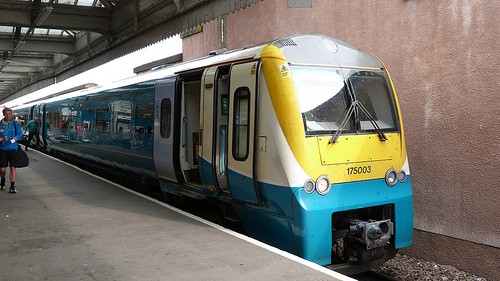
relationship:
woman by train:
[4, 131, 34, 201] [84, 28, 422, 255]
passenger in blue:
[0, 98, 30, 200] [9, 126, 16, 133]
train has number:
[84, 28, 422, 255] [346, 166, 376, 176]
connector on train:
[338, 203, 405, 263] [84, 28, 422, 255]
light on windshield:
[319, 80, 337, 99] [291, 64, 393, 130]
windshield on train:
[286, 64, 401, 137] [84, 28, 422, 255]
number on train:
[346, 166, 376, 176] [84, 28, 422, 255]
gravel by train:
[403, 257, 443, 279] [84, 28, 422, 255]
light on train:
[319, 80, 337, 99] [84, 28, 422, 255]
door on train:
[151, 76, 238, 196] [84, 28, 422, 255]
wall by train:
[438, 28, 494, 145] [84, 28, 422, 255]